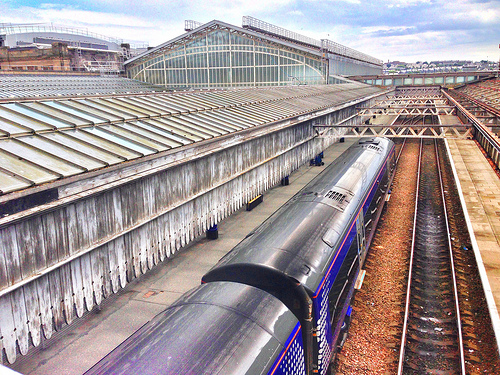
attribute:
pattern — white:
[302, 297, 349, 374]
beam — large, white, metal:
[310, 125, 477, 139]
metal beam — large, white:
[315, 124, 498, 144]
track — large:
[397, 112, 465, 373]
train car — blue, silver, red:
[82, 281, 304, 373]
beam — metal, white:
[377, 93, 457, 100]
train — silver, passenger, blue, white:
[83, 136, 395, 373]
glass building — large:
[123, 16, 386, 93]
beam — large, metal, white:
[364, 99, 446, 140]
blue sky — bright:
[4, 0, 498, 67]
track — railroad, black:
[402, 143, 464, 373]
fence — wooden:
[1, 87, 398, 372]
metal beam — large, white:
[132, 45, 345, 140]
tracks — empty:
[392, 114, 492, 339]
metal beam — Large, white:
[9, 112, 119, 144]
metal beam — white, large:
[372, 86, 455, 116]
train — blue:
[226, 185, 381, 324]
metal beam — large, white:
[14, 100, 147, 157]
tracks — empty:
[403, 198, 463, 338]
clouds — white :
[345, 15, 437, 54]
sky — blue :
[2, 0, 496, 80]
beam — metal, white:
[395, 67, 479, 95]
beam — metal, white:
[363, 105, 462, 120]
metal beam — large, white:
[172, 99, 219, 129]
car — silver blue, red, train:
[195, 187, 391, 372]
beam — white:
[313, 122, 472, 137]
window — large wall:
[149, 36, 306, 82]